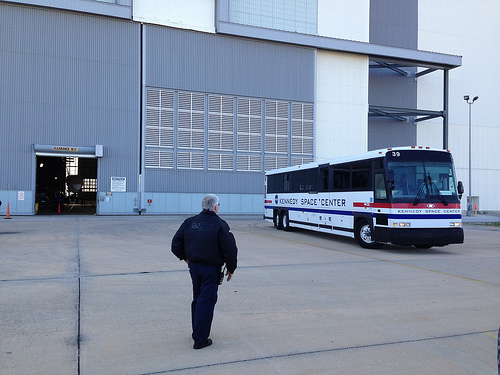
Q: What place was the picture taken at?
A: It was taken at the parking lot.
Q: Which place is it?
A: It is a parking lot.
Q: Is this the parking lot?
A: Yes, it is the parking lot.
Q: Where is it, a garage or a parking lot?
A: It is a parking lot.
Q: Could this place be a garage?
A: No, it is a parking lot.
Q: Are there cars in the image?
A: No, there are no cars.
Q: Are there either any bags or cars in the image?
A: No, there are no cars or bags.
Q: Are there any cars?
A: No, there are no cars.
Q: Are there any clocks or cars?
A: No, there are no cars or clocks.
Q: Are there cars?
A: No, there are no cars.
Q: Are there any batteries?
A: No, there are no batteries.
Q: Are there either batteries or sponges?
A: No, there are no batteries or sponges.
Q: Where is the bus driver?
A: The bus driver is in the bus.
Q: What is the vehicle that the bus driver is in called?
A: The vehicle is a bus.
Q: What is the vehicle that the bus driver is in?
A: The vehicle is a bus.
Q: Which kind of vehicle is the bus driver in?
A: The bus driver is in the bus.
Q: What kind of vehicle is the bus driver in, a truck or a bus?
A: The bus driver is in a bus.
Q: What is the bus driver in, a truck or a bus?
A: The bus driver is in a bus.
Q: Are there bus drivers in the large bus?
A: Yes, there is a bus driver in the bus.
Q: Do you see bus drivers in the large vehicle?
A: Yes, there is a bus driver in the bus.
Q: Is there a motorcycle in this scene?
A: No, there are no motorcycles.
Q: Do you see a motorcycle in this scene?
A: No, there are no motorcycles.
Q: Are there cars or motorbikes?
A: No, there are no motorbikes or cars.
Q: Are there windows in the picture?
A: Yes, there is a window.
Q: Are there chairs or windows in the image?
A: Yes, there is a window.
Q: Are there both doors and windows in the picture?
A: Yes, there are both a window and a door.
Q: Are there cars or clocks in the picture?
A: No, there are no cars or clocks.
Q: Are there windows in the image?
A: Yes, there is a window.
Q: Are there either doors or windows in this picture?
A: Yes, there is a window.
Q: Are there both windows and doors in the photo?
A: Yes, there are both a window and a door.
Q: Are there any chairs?
A: No, there are no chairs.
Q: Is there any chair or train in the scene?
A: No, there are no chairs or trains.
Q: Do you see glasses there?
A: No, there are no glasses.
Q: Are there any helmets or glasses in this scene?
A: No, there are no glasses or helmets.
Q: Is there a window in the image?
A: Yes, there is a window.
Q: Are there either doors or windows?
A: Yes, there is a window.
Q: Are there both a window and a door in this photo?
A: Yes, there are both a window and a door.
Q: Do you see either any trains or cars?
A: No, there are no cars or trains.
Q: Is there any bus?
A: Yes, there is a bus.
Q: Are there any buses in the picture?
A: Yes, there is a bus.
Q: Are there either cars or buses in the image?
A: Yes, there is a bus.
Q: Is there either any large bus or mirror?
A: Yes, there is a large bus.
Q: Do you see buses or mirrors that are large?
A: Yes, the bus is large.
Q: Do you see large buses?
A: Yes, there is a large bus.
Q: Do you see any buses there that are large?
A: Yes, there is a bus that is large.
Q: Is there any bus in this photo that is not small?
A: Yes, there is a large bus.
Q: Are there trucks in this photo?
A: No, there are no trucks.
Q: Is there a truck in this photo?
A: No, there are no trucks.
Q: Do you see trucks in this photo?
A: No, there are no trucks.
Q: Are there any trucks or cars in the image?
A: No, there are no trucks or cars.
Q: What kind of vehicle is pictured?
A: The vehicle is a bus.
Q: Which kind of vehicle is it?
A: The vehicle is a bus.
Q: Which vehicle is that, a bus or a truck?
A: This is a bus.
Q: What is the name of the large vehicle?
A: The vehicle is a bus.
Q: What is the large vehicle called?
A: The vehicle is a bus.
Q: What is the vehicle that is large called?
A: The vehicle is a bus.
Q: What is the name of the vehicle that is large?
A: The vehicle is a bus.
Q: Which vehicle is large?
A: The vehicle is a bus.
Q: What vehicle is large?
A: The vehicle is a bus.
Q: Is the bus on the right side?
A: Yes, the bus is on the right of the image.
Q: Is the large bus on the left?
A: No, the bus is on the right of the image.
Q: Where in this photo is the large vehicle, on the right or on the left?
A: The bus is on the right of the image.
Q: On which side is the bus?
A: The bus is on the right of the image.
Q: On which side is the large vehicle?
A: The bus is on the right of the image.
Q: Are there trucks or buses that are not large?
A: No, there is a bus but it is large.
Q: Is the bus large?
A: Yes, the bus is large.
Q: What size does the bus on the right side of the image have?
A: The bus has large size.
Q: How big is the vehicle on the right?
A: The bus is large.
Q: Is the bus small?
A: No, the bus is large.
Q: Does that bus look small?
A: No, the bus is large.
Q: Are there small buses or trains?
A: No, there is a bus but it is large.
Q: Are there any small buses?
A: No, there is a bus but it is large.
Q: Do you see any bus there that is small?
A: No, there is a bus but it is large.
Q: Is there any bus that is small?
A: No, there is a bus but it is large.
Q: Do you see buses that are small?
A: No, there is a bus but it is large.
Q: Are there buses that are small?
A: No, there is a bus but it is large.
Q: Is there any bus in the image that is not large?
A: No, there is a bus but it is large.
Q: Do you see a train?
A: No, there are no trains.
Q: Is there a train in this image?
A: No, there are no trains.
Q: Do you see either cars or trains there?
A: No, there are no trains or cars.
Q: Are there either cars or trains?
A: No, there are no trains or cars.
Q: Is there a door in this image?
A: Yes, there is a door.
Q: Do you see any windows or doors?
A: Yes, there is a door.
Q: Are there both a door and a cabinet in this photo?
A: No, there is a door but no cabinets.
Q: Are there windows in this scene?
A: Yes, there is a window.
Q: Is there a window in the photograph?
A: Yes, there is a window.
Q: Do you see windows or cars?
A: Yes, there is a window.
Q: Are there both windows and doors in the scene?
A: Yes, there are both a window and a door.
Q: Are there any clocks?
A: No, there are no clocks.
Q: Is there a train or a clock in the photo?
A: No, there are no clocks or trains.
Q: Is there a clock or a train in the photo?
A: No, there are no clocks or trains.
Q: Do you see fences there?
A: No, there are no fences.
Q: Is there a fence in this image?
A: No, there are no fences.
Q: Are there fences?
A: No, there are no fences.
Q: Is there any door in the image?
A: Yes, there is a door.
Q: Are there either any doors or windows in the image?
A: Yes, there is a door.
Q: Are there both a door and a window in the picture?
A: Yes, there are both a door and a window.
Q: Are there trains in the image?
A: No, there are no trains.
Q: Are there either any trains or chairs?
A: No, there are no trains or chairs.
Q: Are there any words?
A: Yes, there are words.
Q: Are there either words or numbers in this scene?
A: Yes, there are words.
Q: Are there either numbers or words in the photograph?
A: Yes, there are words.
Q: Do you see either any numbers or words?
A: Yes, there are words.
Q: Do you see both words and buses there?
A: Yes, there are both words and a bus.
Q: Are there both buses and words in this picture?
A: Yes, there are both words and a bus.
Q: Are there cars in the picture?
A: No, there are no cars.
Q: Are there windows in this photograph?
A: Yes, there is a window.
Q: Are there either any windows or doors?
A: Yes, there is a window.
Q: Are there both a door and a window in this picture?
A: Yes, there are both a window and a door.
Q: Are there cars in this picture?
A: No, there are no cars.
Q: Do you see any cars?
A: No, there are no cars.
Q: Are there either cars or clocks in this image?
A: No, there are no cars or clocks.